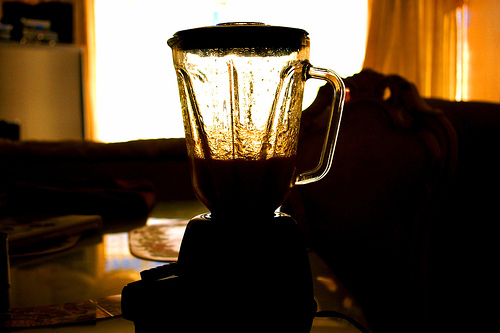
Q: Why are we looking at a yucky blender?
A: Because we are trying to make some extra money.